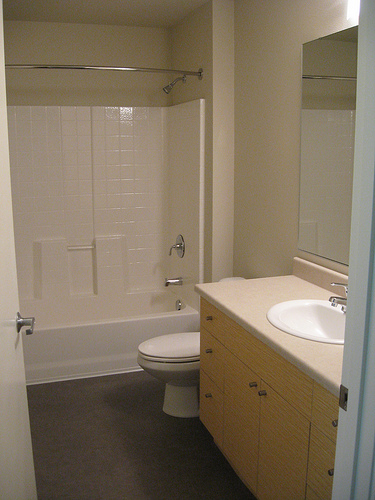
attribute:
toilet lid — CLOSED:
[134, 330, 198, 375]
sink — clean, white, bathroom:
[264, 296, 344, 345]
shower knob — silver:
[163, 231, 188, 260]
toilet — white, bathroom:
[134, 328, 204, 418]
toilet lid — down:
[136, 329, 204, 358]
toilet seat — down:
[135, 326, 200, 362]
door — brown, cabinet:
[256, 378, 310, 494]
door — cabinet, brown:
[223, 349, 258, 487]